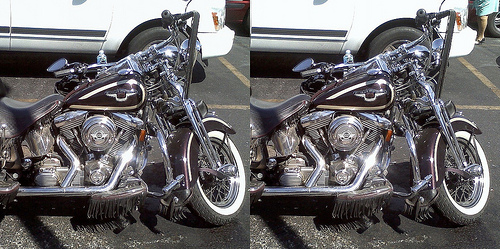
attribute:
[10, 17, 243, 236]
bike — black, parked, older styled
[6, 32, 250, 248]
pavement — concrete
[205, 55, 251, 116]
lines — worn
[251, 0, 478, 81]
vehicle — white, parked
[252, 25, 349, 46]
stripe — black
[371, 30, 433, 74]
tire — black, washed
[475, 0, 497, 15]
skirt — blue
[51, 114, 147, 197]
engine — silver, metal, chrome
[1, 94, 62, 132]
seat — black, leather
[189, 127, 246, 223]
tire — white wall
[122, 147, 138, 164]
sunshine — reflected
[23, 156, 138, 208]
exhaust pipe — chrome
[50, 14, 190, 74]
handle bars — chrome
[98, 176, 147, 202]
footboard — chrome